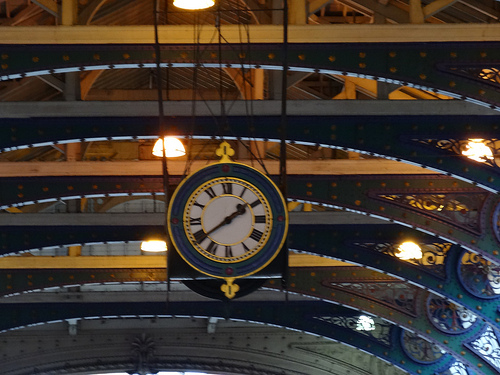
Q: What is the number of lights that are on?
A: Six.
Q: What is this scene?
A: A ceiling.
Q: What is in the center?
A: A clock.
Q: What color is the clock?
A: Gold, white, and green.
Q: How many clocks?
A: One.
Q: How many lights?
A: Six.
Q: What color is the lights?
A: Yellow.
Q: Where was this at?
A: Indoors inside building.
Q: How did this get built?
A: By builders.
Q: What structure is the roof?
A: Arched.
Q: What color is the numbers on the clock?
A: Black.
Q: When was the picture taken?
A: At 1:40.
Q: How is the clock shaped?
A: Round.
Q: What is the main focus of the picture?
A: A clock.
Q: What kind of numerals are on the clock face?
A: Roman.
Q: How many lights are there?
A: 6.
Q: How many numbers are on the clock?
A: 12.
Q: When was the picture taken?
A: Daytime.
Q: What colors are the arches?
A: Blue and gray.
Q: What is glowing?
A: The lights.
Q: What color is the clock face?
A: White and gold.